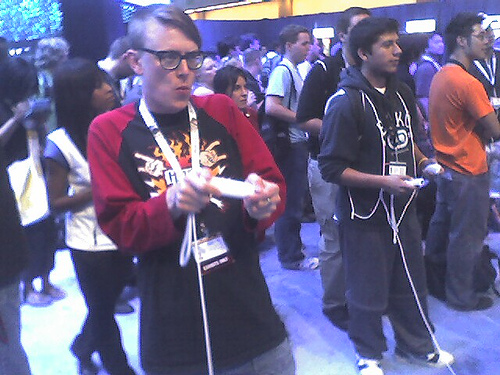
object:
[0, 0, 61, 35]
trees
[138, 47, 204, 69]
glasses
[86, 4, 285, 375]
boy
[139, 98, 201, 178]
lanyard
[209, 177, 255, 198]
controller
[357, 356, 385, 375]
shoe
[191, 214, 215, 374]
cord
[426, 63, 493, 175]
shirt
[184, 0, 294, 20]
paint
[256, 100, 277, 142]
bag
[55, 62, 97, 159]
hair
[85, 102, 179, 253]
sleeve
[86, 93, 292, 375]
shirt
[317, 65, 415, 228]
hoodie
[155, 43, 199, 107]
face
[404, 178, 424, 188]
games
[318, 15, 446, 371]
man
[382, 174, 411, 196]
hand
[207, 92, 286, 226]
arm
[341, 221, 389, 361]
leg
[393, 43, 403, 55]
nose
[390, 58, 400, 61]
mouth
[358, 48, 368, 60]
ear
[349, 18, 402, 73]
head